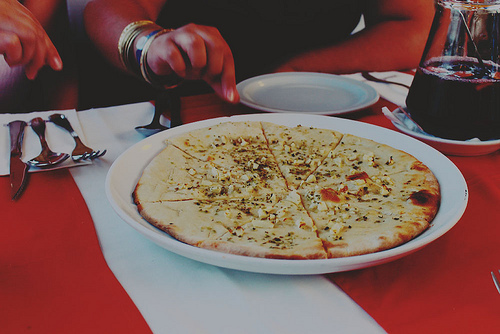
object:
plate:
[104, 108, 472, 277]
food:
[133, 117, 442, 259]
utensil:
[6, 118, 28, 202]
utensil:
[26, 116, 71, 170]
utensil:
[49, 111, 105, 162]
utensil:
[134, 93, 166, 137]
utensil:
[167, 90, 184, 129]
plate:
[230, 70, 382, 118]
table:
[0, 68, 499, 333]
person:
[81, 0, 456, 104]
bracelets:
[141, 27, 180, 90]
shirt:
[155, 1, 367, 83]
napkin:
[1, 106, 94, 173]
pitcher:
[403, 2, 498, 142]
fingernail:
[225, 87, 243, 104]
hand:
[147, 19, 242, 112]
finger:
[218, 33, 240, 108]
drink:
[404, 57, 500, 143]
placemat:
[0, 157, 149, 332]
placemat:
[149, 69, 499, 334]